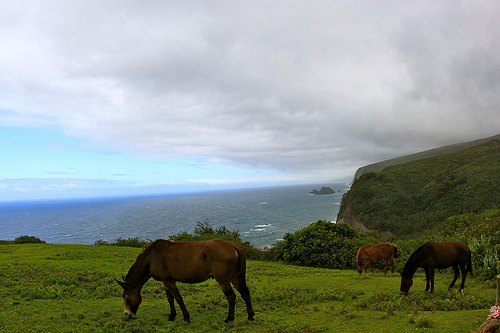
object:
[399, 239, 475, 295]
horse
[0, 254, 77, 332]
grass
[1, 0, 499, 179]
cloud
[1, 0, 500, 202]
sky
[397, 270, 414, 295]
head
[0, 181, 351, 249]
water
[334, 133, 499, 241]
cliff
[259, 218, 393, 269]
bush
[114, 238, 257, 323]
horse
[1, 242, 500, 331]
field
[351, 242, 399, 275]
horse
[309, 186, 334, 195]
boulder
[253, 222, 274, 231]
cap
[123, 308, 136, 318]
mouth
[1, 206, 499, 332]
hill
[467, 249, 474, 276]
tail